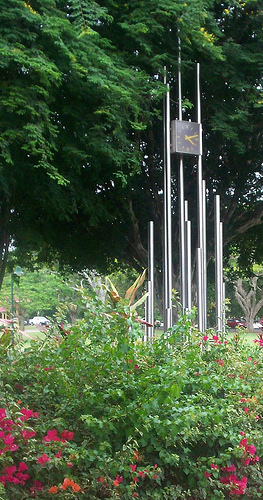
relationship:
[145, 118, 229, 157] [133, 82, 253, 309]
clock on poles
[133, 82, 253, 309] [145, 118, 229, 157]
poles with clock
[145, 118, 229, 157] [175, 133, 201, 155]
clock has hands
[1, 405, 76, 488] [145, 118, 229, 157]
flowers below clock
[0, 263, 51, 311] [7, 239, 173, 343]
post in park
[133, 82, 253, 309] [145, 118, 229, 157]
poles have clock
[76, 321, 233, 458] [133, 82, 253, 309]
bush below poles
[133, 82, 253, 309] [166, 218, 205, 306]
poles in threes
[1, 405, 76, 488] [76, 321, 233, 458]
flowers in bush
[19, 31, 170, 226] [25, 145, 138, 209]
tree has branches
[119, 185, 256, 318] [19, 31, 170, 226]
chime by tree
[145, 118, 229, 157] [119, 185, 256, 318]
clock on chime